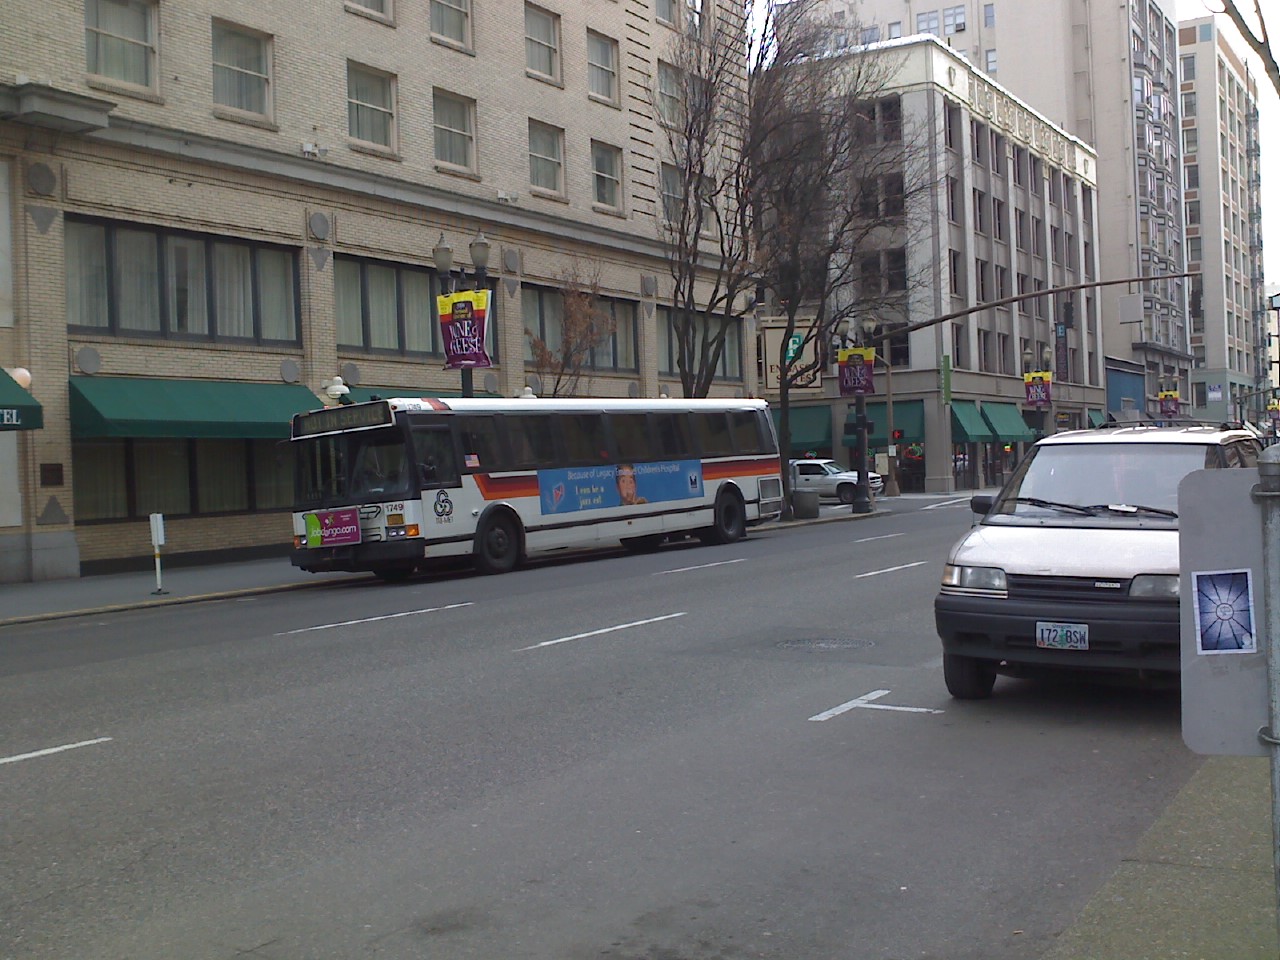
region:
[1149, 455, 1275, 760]
A back of the sign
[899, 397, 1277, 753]
The parked white vehicle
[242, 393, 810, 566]
The public bus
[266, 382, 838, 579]
A public bus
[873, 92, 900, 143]
window facing busy street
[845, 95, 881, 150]
window facing busy street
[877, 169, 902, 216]
window facing busy street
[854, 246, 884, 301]
window facing busy street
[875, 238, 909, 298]
window facing busy street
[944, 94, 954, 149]
window facing busy street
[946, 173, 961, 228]
window facing busy street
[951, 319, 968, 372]
window facing busy street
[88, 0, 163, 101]
window on brick building facing street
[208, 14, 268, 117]
window on brick building facing street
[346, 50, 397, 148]
window on brick building facing street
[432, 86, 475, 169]
window on brick building facing street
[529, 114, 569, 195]
window on brick building facing street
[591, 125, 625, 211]
window on brick building facing street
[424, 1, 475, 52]
window on brick building facing street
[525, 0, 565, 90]
window on brick building facing street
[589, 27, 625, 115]
window on brick building facing street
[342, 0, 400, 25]
window on brick building facing street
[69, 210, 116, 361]
a window on a building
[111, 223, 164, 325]
a window on a building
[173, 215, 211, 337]
a window on a building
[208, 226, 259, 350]
a window on a building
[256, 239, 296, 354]
a window on a building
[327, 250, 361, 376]
a window on a building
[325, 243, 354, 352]
a window on a building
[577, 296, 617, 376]
a window on a building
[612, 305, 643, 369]
a window on a building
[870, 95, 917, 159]
a window on a building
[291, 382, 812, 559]
bus parked on the curb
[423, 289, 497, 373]
banner attached to the street light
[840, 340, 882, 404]
banner attached to the street light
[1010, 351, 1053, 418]
banner attached to the street light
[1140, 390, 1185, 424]
banner attached to the street light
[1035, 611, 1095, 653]
license plate on the car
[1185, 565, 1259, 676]
sticker on the sign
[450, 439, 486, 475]
flag on the bus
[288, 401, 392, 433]
electric display on the bus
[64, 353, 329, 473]
awning on the building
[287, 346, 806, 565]
bus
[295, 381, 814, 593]
transit bus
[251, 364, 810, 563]
transit bus parked on street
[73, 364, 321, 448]
green awning on window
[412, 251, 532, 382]
colorful flag on street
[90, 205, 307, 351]
windows in tan colored building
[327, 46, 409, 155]
windows in tan colored building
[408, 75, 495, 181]
windows in tan colored building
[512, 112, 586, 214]
windows in tan colored building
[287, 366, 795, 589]
the bus is stopped by the sidwalk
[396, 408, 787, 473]
a row of windows is on the bus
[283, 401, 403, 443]
the sign display is above the window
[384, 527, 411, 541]
a light is in front of the bus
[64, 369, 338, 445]
a canopy is above the window display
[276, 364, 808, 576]
a bus parked on the side of a street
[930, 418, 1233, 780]
a vehicle parked next to a curb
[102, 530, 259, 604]
a concrete sidwalk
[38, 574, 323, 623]
a concrete curb next to a street